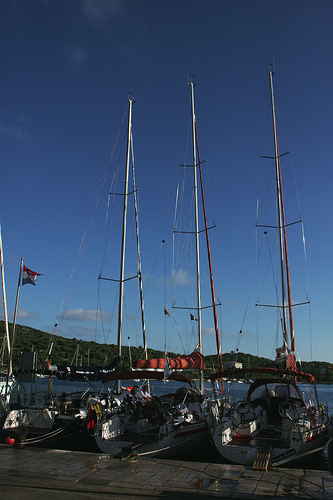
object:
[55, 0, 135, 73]
cloud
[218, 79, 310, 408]
sails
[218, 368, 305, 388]
sail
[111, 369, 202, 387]
sail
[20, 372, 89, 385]
sail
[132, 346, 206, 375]
sail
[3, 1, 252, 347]
clouds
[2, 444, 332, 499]
dock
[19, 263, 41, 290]
flag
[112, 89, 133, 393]
mast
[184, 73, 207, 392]
mast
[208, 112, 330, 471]
boat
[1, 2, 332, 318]
sky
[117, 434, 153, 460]
ramp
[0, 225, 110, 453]
boats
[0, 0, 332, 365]
clouds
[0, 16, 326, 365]
cloud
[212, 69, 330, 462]
sailboat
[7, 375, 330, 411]
water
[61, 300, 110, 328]
clouds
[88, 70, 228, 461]
sailboat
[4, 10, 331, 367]
area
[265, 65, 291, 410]
mast